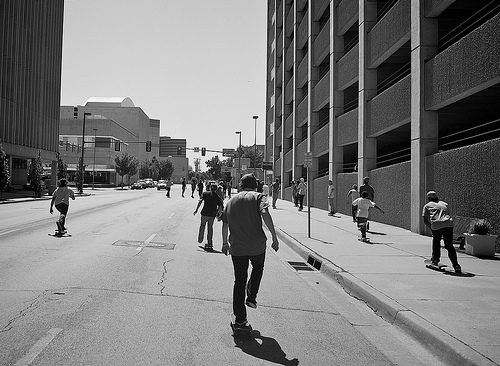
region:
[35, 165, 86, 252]
a person skateboarding on the road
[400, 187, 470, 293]
a person skateboarding on the pavement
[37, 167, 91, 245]
a person skateboarding on the street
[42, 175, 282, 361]
people skateboarding on the street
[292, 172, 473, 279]
people skateboarding on the pavement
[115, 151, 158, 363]
cars parked in the distance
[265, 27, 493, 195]
car parking garage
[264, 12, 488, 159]
the side of a car parking garage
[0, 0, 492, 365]
This is in the city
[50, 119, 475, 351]
These kids are skateboarding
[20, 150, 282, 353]
These kids are in the street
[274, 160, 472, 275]
These kids are on the sidewalk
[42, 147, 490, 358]
These kids are skateboarders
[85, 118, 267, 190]
These are street lights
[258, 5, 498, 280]
This is a parking garage building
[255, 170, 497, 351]
This is the sidewalk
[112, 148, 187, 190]
There are trees in the distance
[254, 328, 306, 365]
Small dark man shadow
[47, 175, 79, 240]
A person on skates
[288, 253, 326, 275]
Small pothole on sidewalk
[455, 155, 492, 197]
Grey plastered stone wall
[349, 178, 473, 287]
People skating on sidewalk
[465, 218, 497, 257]
Flowers growing on vase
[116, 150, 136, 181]
Trees growing on sidewalk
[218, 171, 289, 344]
person on a skateboard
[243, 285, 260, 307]
leg is in the air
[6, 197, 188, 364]
dotted line on the street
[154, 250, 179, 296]
crack in the road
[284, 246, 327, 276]
sewer on the curb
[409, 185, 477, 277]
person skateboarding on the sidewalk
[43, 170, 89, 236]
person skateboarding on the street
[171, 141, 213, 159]
two traffic lights on a pole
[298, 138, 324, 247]
pole sticking out of the sidewalk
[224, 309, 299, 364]
shadow from the skateboarder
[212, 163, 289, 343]
person on a skateboard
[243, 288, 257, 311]
leg is in the air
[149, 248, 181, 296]
crack in the street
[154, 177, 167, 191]
car on the road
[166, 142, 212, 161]
two traffic lights on a pole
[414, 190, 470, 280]
person skateboarding on the sidewalk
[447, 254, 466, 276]
back leg on the ground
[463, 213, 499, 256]
plant in a planter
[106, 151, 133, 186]
tree on the sidewalk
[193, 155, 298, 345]
Man on a skateboard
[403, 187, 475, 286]
Man on a skateboard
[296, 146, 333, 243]
Sign on a pole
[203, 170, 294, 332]
Man wearing black pants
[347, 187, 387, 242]
Boy wearing white shirt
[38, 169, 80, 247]
Person wearing white shirt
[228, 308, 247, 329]
a long grey skateboard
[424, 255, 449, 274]
skateboard on a sidewalk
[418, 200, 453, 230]
a shirt on a person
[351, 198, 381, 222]
a white shirt on a boy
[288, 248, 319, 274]
drains in a ditch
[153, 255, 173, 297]
a crack in the street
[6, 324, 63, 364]
white paint on the road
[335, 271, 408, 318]
a crack in a curb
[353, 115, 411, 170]
A window on a building.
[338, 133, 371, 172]
A window on a building.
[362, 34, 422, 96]
A window on a building.